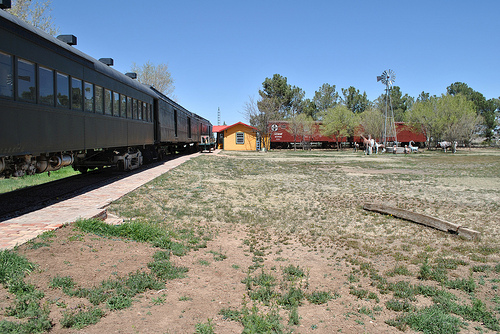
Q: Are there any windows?
A: Yes, there is a window.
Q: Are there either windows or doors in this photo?
A: Yes, there is a window.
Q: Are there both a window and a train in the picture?
A: Yes, there are both a window and a train.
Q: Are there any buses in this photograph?
A: No, there are no buses.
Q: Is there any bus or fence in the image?
A: No, there are no buses or fences.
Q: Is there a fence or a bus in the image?
A: No, there are no buses or fences.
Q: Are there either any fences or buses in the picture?
A: No, there are no buses or fences.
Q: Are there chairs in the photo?
A: No, there are no chairs.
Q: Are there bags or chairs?
A: No, there are no chairs or bags.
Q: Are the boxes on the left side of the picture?
A: Yes, the boxes are on the left of the image.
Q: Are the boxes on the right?
A: No, the boxes are on the left of the image.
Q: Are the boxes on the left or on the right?
A: The boxes are on the left of the image.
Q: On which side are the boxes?
A: The boxes are on the left of the image.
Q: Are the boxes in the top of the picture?
A: Yes, the boxes are in the top of the image.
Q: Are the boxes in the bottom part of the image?
A: No, the boxes are in the top of the image.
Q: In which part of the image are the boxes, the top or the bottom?
A: The boxes are in the top of the image.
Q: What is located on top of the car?
A: The boxes are on top of the car.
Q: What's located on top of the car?
A: The boxes are on top of the car.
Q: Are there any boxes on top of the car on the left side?
A: Yes, there are boxes on top of the car.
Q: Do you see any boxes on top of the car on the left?
A: Yes, there are boxes on top of the car.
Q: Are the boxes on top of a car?
A: Yes, the boxes are on top of a car.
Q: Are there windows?
A: Yes, there is a window.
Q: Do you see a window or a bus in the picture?
A: Yes, there is a window.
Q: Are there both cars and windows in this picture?
A: Yes, there are both a window and a car.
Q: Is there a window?
A: Yes, there is a window.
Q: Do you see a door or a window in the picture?
A: Yes, there is a window.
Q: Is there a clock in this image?
A: No, there are no clocks.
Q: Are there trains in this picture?
A: Yes, there is a train.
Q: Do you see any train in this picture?
A: Yes, there is a train.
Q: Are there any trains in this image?
A: Yes, there is a train.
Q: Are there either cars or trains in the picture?
A: Yes, there is a train.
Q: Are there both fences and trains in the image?
A: No, there is a train but no fences.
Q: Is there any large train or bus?
A: Yes, there is a large train.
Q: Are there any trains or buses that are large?
A: Yes, the train is large.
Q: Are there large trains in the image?
A: Yes, there is a large train.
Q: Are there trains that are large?
A: Yes, there is a train that is large.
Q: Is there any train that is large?
A: Yes, there is a train that is large.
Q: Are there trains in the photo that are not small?
A: Yes, there is a large train.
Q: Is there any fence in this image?
A: No, there are no fences.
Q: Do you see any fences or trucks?
A: No, there are no fences or trucks.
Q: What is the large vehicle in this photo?
A: The vehicle is a train.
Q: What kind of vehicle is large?
A: The vehicle is a train.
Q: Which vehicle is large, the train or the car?
A: The train is large.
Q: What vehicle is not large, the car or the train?
A: The car is not large.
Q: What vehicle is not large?
A: The vehicle is a car.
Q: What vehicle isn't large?
A: The vehicle is a car.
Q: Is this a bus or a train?
A: This is a train.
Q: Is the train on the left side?
A: Yes, the train is on the left of the image.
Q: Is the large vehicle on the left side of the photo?
A: Yes, the train is on the left of the image.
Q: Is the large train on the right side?
A: No, the train is on the left of the image.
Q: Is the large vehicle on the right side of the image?
A: No, the train is on the left of the image.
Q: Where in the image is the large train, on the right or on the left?
A: The train is on the left of the image.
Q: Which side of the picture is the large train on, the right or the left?
A: The train is on the left of the image.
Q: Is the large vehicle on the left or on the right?
A: The train is on the left of the image.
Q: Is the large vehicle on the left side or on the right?
A: The train is on the left of the image.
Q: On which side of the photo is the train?
A: The train is on the left of the image.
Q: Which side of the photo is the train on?
A: The train is on the left of the image.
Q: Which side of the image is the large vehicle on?
A: The train is on the left of the image.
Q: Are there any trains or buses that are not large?
A: No, there is a train but it is large.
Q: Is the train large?
A: Yes, the train is large.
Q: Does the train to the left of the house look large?
A: Yes, the train is large.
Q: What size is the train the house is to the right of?
A: The train is large.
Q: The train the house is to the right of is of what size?
A: The train is large.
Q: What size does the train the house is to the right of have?
A: The train has large size.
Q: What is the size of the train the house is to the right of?
A: The train is large.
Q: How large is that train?
A: The train is large.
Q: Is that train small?
A: No, the train is large.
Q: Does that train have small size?
A: No, the train is large.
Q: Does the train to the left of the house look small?
A: No, the train is large.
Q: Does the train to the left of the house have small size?
A: No, the train is large.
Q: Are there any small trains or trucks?
A: No, there is a train but it is large.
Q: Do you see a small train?
A: No, there is a train but it is large.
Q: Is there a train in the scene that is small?
A: No, there is a train but it is large.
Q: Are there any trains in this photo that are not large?
A: No, there is a train but it is large.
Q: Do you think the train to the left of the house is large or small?
A: The train is large.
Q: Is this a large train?
A: Yes, this is a large train.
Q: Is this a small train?
A: No, this is a large train.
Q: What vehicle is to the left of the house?
A: The vehicle is a train.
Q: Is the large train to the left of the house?
A: Yes, the train is to the left of the house.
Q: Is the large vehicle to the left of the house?
A: Yes, the train is to the left of the house.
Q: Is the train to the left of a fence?
A: No, the train is to the left of the house.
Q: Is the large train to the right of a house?
A: No, the train is to the left of a house.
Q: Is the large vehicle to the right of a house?
A: No, the train is to the left of a house.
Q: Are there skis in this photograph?
A: No, there are no skis.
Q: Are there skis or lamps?
A: No, there are no skis or lamps.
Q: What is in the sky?
A: The clouds are in the sky.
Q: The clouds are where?
A: The clouds are in the sky.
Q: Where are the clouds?
A: The clouds are in the sky.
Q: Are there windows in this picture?
A: Yes, there is a window.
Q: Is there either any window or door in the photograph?
A: Yes, there is a window.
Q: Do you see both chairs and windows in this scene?
A: No, there is a window but no chairs.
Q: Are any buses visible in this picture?
A: No, there are no buses.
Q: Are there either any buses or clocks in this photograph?
A: No, there are no buses or clocks.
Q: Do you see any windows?
A: Yes, there is a window.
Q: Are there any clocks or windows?
A: Yes, there is a window.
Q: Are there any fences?
A: No, there are no fences.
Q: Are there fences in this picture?
A: No, there are no fences.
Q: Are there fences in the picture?
A: No, there are no fences.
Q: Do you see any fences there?
A: No, there are no fences.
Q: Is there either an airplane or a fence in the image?
A: No, there are no fences or airplanes.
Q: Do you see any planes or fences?
A: No, there are no fences or planes.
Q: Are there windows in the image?
A: Yes, there is a window.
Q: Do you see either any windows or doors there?
A: Yes, there is a window.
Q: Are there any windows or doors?
A: Yes, there is a window.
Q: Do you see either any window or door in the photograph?
A: Yes, there is a window.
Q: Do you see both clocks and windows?
A: No, there is a window but no clocks.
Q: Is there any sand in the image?
A: Yes, there is sand.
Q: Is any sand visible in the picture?
A: Yes, there is sand.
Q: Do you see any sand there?
A: Yes, there is sand.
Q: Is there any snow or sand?
A: Yes, there is sand.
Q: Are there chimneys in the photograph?
A: No, there are no chimneys.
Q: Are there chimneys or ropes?
A: No, there are no chimneys or ropes.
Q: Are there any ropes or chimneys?
A: No, there are no chimneys or ropes.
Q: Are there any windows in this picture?
A: Yes, there is a window.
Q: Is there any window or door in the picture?
A: Yes, there is a window.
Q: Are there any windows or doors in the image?
A: Yes, there is a window.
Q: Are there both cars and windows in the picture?
A: Yes, there are both a window and a car.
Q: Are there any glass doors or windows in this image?
A: Yes, there is a glass window.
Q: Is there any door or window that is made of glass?
A: Yes, the window is made of glass.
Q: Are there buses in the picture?
A: No, there are no buses.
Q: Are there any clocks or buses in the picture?
A: No, there are no buses or clocks.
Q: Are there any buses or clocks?
A: No, there are no buses or clocks.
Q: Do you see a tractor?
A: No, there are no tractors.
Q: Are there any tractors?
A: No, there are no tractors.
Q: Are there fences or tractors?
A: No, there are no tractors or fences.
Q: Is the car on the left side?
A: Yes, the car is on the left of the image.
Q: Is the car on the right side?
A: No, the car is on the left of the image.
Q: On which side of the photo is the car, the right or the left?
A: The car is on the left of the image.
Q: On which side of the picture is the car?
A: The car is on the left of the image.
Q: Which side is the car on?
A: The car is on the left of the image.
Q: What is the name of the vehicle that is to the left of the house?
A: The vehicle is a car.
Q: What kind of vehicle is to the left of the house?
A: The vehicle is a car.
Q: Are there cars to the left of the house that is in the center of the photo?
A: Yes, there is a car to the left of the house.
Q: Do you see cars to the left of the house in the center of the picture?
A: Yes, there is a car to the left of the house.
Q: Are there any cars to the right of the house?
A: No, the car is to the left of the house.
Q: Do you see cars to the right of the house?
A: No, the car is to the left of the house.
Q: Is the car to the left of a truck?
A: No, the car is to the left of the house.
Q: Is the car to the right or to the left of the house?
A: The car is to the left of the house.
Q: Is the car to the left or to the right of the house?
A: The car is to the left of the house.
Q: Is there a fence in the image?
A: No, there are no fences.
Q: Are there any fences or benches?
A: No, there are no fences or benches.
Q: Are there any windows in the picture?
A: Yes, there is a window.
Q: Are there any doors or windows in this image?
A: Yes, there is a window.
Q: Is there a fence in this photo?
A: No, there are no fences.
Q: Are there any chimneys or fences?
A: No, there are no fences or chimneys.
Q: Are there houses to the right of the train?
A: Yes, there is a house to the right of the train.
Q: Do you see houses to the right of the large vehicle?
A: Yes, there is a house to the right of the train.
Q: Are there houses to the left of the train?
A: No, the house is to the right of the train.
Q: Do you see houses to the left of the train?
A: No, the house is to the right of the train.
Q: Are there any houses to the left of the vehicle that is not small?
A: No, the house is to the right of the train.